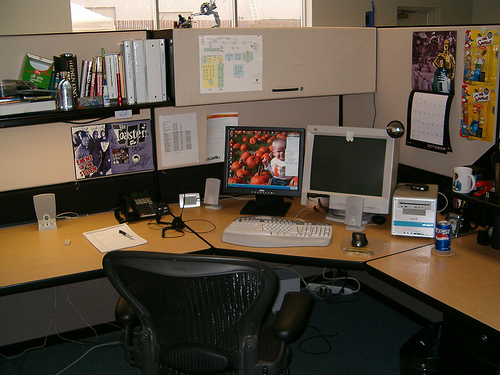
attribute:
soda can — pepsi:
[431, 220, 452, 253]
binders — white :
[123, 36, 168, 109]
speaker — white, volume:
[31, 177, 70, 244]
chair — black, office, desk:
[85, 251, 329, 362]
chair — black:
[105, 237, 314, 374]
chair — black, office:
[99, 246, 321, 373]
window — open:
[68, 2, 315, 32]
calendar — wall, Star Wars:
[398, 23, 462, 155]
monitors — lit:
[214, 101, 395, 229]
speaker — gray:
[30, 190, 60, 232]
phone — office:
[116, 180, 175, 232]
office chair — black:
[100, 248, 313, 373]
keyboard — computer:
[220, 210, 334, 252]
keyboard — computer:
[220, 214, 333, 249]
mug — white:
[450, 162, 483, 200]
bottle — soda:
[429, 219, 454, 250]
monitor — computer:
[219, 124, 306, 197]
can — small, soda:
[432, 217, 455, 253]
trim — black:
[220, 119, 308, 198]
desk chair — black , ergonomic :
[101, 228, 314, 372]